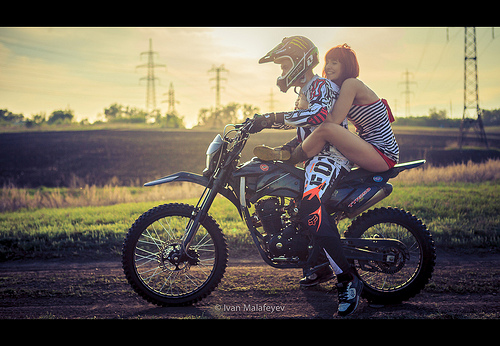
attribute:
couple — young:
[253, 36, 407, 171]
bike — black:
[113, 119, 441, 315]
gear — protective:
[263, 36, 365, 304]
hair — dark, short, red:
[327, 47, 361, 77]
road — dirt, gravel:
[3, 256, 495, 317]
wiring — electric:
[409, 30, 461, 79]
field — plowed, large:
[2, 121, 494, 178]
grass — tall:
[4, 176, 154, 208]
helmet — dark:
[262, 35, 321, 89]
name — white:
[220, 303, 286, 315]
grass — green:
[4, 204, 125, 253]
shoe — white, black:
[338, 272, 363, 315]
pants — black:
[299, 159, 350, 279]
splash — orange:
[303, 183, 326, 204]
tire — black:
[119, 203, 227, 306]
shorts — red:
[371, 145, 398, 169]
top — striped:
[347, 102, 401, 157]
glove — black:
[247, 113, 276, 133]